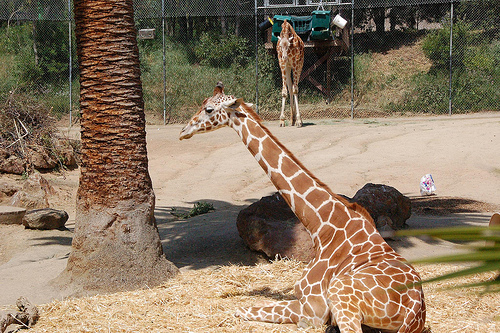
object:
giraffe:
[176, 81, 426, 332]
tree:
[62, 0, 179, 300]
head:
[178, 78, 245, 139]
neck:
[233, 108, 357, 240]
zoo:
[0, 1, 500, 332]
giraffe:
[275, 18, 307, 129]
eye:
[206, 106, 218, 114]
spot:
[260, 134, 282, 173]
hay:
[2, 253, 500, 332]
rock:
[23, 208, 67, 231]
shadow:
[29, 194, 493, 272]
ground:
[0, 110, 500, 333]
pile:
[0, 85, 86, 176]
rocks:
[237, 182, 415, 264]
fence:
[0, 1, 500, 126]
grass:
[0, 212, 500, 332]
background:
[0, 0, 500, 230]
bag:
[419, 174, 438, 195]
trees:
[0, 0, 500, 123]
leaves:
[357, 13, 500, 112]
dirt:
[0, 109, 500, 305]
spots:
[232, 116, 426, 332]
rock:
[235, 187, 376, 265]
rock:
[351, 181, 415, 230]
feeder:
[271, 11, 336, 46]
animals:
[177, 19, 427, 332]